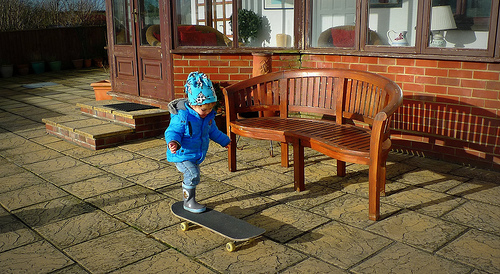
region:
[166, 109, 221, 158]
Blue jacket in the photo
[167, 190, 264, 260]
A skate board on the floor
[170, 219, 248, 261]
Skate board wheels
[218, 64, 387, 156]
Wooden bench in the photo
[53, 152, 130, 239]
A paved floor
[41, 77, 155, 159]
Stairs on the doorstep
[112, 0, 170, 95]
A door in the photo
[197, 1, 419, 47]
Glass panes in the photo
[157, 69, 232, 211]
A child in the photo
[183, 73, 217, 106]
A blue hat in the photo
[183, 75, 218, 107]
the toddler is wearing a hat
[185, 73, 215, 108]
the hat is blue in color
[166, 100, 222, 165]
the toddler is wearing a blue jacket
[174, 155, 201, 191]
the toddler is wearing long pants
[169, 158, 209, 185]
the pants are blue in color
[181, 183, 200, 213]
the toddler is wearing boots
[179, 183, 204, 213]
the boots are black in color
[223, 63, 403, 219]
the bench is made of wood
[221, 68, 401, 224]
the bench is brown in color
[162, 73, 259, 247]
the toddler is on a skateboard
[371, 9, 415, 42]
the windows have no curtains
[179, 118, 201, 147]
the coat is blue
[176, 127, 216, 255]
the kid is putting her foot on the skateboard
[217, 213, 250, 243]
the skateboard is gray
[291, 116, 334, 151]
the bench is brown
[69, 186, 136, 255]
the patio is made of stones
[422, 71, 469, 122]
the house is made of bricks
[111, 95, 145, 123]
the mat is black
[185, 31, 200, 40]
the pillows are red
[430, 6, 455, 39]
the lamp is white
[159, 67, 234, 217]
a little kid riding a skateboard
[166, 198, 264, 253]
the skateboard the kid is playing with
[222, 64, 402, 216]
the bench next to the building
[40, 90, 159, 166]
the steps laying next to the door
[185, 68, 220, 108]
the hat on the kids head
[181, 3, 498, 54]
the windows for people to look out of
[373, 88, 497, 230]
the shadow of the bench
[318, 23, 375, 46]
the red chair in the room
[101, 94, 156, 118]
the door mat on the step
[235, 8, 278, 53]
a plant by the window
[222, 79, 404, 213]
rocking wooden chair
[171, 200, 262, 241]
A black sketing board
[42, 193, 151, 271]
A clean stone tiled ground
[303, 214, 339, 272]
A clean stone tiled ground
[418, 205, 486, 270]
A clean stone tiled ground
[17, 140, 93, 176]
A clean stone tiled ground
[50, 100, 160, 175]
A clean stone tiled door steps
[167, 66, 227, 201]
A small warmly dressed boy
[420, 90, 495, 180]
A wooden chair shadow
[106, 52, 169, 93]
A wooden brown door